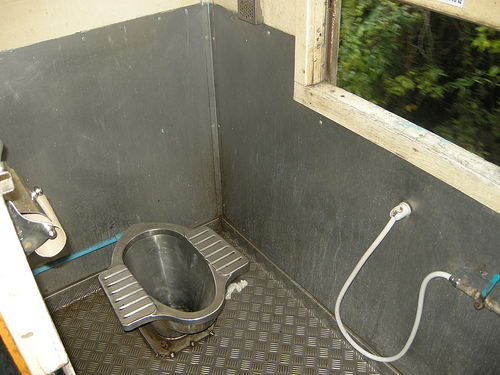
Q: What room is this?
A: A toilet.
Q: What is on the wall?
A: A window.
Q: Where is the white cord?
A: Plugged in to the wall.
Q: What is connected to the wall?
A: A white cord.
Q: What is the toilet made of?
A: Metal.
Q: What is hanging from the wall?
A: Toilet paper.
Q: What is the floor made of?
A: Metal.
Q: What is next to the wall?
A: The toilet.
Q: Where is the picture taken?
A: A bathroom.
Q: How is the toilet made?
A: Of steel.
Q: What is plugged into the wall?
A: A white cord.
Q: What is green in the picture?
A: Trees.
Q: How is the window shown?
A: Open.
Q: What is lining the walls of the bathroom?
A: Steel.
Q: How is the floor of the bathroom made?
A: Of metal.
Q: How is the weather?
A: Clear and sunny.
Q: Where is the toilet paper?
A: On the wall.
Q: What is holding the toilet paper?
A: Metal roller.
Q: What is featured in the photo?
A: A bathroom.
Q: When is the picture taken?
A: During the day.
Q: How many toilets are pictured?
A: One.